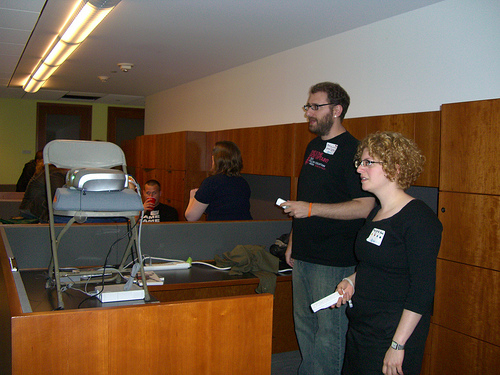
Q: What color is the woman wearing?
A: Black.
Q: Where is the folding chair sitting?
A: On desk.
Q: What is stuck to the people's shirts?
A: Name tags.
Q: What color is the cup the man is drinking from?
A: Red.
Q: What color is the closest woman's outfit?
A: Black.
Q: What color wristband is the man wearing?
A: Orange.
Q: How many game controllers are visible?
A: 2.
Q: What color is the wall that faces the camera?
A: Yellow.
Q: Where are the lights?
A: Ceiling.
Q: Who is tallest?
A: The man.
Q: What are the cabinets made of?
A: Wood.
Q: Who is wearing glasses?
A: Man in black shirt.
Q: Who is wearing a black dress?
A: Woman with curly hair.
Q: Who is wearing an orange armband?
A: Man with glasses.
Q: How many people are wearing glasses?
A: Two.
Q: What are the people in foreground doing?
A: Playing video game.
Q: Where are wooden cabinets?
A: Behind the people.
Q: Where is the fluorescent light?
A: On ceiling.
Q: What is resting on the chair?
A: A projector.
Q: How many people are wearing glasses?
A: Two.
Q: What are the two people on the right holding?
A: Wii game controllers.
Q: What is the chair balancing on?
A: A cabinet.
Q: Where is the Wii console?
A: Under the chair.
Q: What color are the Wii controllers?
A: White.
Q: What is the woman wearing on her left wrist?
A: A watch.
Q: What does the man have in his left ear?
A: An earring.